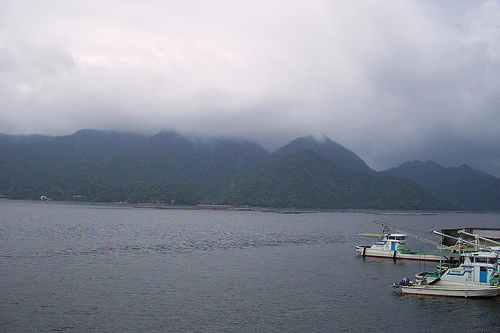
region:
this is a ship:
[345, 218, 435, 273]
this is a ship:
[392, 264, 496, 311]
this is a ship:
[432, 208, 494, 264]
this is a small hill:
[245, 145, 417, 225]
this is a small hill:
[84, 128, 209, 216]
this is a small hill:
[14, 125, 122, 189]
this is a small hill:
[400, 145, 494, 222]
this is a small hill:
[262, 122, 362, 205]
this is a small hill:
[136, 88, 253, 211]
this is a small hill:
[22, 90, 132, 181]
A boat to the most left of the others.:
[353, 215, 445, 260]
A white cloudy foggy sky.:
[0, 0, 494, 163]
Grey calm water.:
[1, 198, 496, 331]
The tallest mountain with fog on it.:
[277, 129, 367, 167]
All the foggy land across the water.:
[1, 127, 498, 212]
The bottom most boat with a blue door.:
[391, 260, 499, 295]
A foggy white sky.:
[2, 1, 499, 165]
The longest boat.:
[356, 230, 452, 262]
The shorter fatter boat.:
[395, 248, 499, 295]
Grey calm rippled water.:
[7, 195, 497, 331]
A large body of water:
[1, 196, 499, 331]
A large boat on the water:
[389, 243, 499, 283]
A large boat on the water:
[358, 220, 450, 262]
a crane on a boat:
[368, 218, 445, 249]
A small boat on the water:
[394, 274, 498, 295]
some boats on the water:
[131, 198, 309, 213]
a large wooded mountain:
[5, 132, 499, 215]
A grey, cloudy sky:
[1, 1, 498, 171]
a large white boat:
[357, 224, 444, 262]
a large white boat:
[416, 252, 498, 287]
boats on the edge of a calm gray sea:
[5, 200, 496, 326]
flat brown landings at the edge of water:
[115, 190, 495, 215]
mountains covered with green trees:
[0, 127, 495, 207]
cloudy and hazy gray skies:
[1, 5, 491, 165]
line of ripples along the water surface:
[25, 230, 340, 255]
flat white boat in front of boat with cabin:
[385, 255, 495, 295]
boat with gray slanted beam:
[347, 210, 452, 281]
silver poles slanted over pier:
[430, 220, 495, 251]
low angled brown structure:
[435, 221, 495, 246]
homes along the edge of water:
[21, 190, 86, 200]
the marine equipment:
[354, 218, 498, 300]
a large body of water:
[0, 200, 497, 332]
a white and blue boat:
[391, 247, 498, 296]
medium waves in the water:
[2, 229, 372, 256]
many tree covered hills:
[0, 127, 495, 215]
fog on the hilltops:
[0, 114, 499, 172]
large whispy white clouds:
[1, 0, 498, 137]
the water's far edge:
[0, 189, 497, 216]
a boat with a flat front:
[354, 223, 449, 262]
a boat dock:
[436, 221, 499, 254]